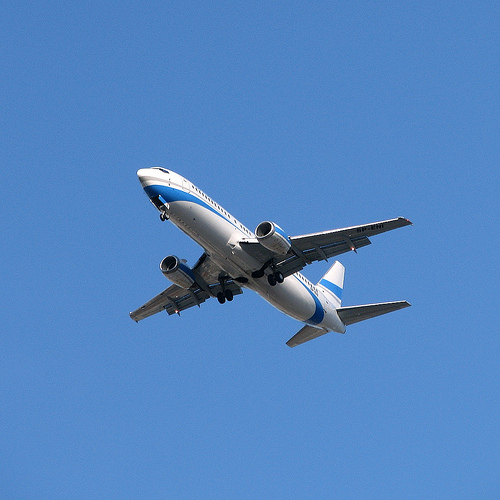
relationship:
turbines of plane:
[159, 255, 195, 292] [122, 160, 414, 362]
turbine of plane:
[248, 217, 302, 264] [122, 160, 414, 362]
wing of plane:
[268, 215, 413, 282] [122, 160, 414, 362]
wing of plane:
[129, 255, 242, 322] [122, 160, 414, 362]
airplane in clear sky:
[129, 166, 412, 350] [0, 0, 498, 495]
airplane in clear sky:
[129, 160, 411, 349] [0, 0, 498, 495]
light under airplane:
[346, 236, 356, 254] [129, 160, 411, 349]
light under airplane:
[172, 307, 182, 314] [129, 160, 411, 349]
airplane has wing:
[129, 166, 412, 350] [277, 206, 407, 269]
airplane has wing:
[129, 160, 411, 349] [129, 246, 244, 335]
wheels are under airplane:
[158, 215, 171, 222] [129, 160, 411, 349]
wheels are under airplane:
[209, 261, 288, 308] [129, 160, 411, 349]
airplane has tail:
[129, 160, 411, 349] [315, 259, 350, 311]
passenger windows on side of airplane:
[195, 183, 250, 233] [129, 166, 412, 350]